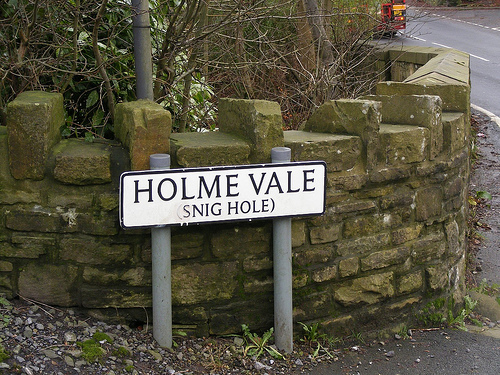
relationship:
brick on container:
[335, 278, 399, 303] [5, 50, 475, 330]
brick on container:
[364, 243, 410, 270] [5, 50, 475, 330]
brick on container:
[312, 220, 344, 242] [5, 50, 475, 330]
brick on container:
[410, 227, 451, 259] [5, 50, 475, 330]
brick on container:
[374, 185, 416, 208] [5, 50, 475, 330]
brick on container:
[9, 232, 60, 244] [5, 50, 475, 330]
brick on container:
[305, 97, 385, 134] [5, 50, 475, 330]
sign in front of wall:
[119, 157, 327, 225] [367, 42, 473, 324]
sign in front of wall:
[119, 157, 327, 225] [3, 94, 384, 343]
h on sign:
[132, 178, 154, 203] [116, 160, 331, 228]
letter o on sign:
[155, 178, 177, 201] [116, 160, 331, 228]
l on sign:
[180, 177, 194, 201] [115, 148, 327, 355]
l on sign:
[285, 171, 299, 193] [115, 148, 327, 355]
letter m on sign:
[198, 173, 221, 201] [116, 160, 331, 228]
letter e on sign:
[224, 170, 242, 198] [115, 148, 327, 355]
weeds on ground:
[239, 324, 284, 364] [1, 304, 498, 373]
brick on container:
[328, 185, 423, 295] [5, 50, 475, 330]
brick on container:
[415, 191, 445, 215] [5, 50, 475, 330]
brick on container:
[394, 304, 468, 331] [4, 27, 498, 330]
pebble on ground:
[61, 328, 78, 343] [4, 311, 134, 372]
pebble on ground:
[0, 298, 147, 375] [4, 311, 134, 372]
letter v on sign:
[246, 167, 268, 195] [112, 157, 334, 231]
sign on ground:
[117, 157, 327, 231] [129, 317, 311, 364]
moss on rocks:
[81, 334, 129, 360] [57, 322, 147, 371]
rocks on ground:
[8, 35, 478, 330] [6, 314, 191, 370]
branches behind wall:
[28, 9, 410, 130] [0, 38, 472, 348]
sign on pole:
[117, 157, 327, 231] [268, 214, 309, 355]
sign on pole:
[117, 157, 327, 231] [149, 226, 171, 347]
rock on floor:
[0, 280, 383, 369] [400, 311, 441, 371]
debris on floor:
[247, 293, 477, 372] [400, 311, 441, 371]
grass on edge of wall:
[449, 292, 479, 327] [7, 75, 471, 335]